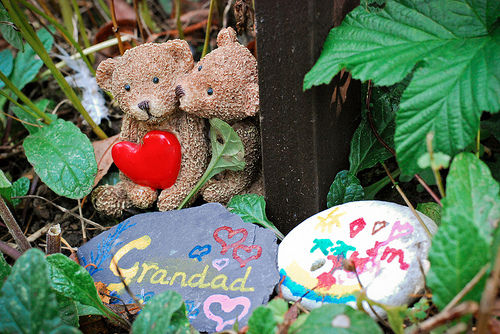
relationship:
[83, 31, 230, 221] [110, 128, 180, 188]
bear has heart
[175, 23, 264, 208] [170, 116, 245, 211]
stuffed animal in leaf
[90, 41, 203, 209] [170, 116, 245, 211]
stuffed animal in leaf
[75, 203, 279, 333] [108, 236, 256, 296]
rock with writing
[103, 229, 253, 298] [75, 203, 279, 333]
word written on rock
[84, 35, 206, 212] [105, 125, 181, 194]
bear holding heart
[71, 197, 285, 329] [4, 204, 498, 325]
rock on ground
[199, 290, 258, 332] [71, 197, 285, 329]
heart on rock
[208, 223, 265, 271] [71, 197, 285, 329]
hearts on rock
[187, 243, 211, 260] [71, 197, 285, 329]
heart on rock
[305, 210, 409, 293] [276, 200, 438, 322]
picture on painted rock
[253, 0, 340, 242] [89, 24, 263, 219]
post next to bears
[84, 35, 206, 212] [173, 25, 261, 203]
bear kissing bear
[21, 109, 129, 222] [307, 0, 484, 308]
leaves of plant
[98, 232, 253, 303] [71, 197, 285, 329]
word on rock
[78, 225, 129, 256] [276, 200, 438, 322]
blue writing on painted rock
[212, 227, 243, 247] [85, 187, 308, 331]
heart on stone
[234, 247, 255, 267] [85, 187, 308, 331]
heart on stone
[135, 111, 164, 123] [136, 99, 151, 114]
mouth on teddy bear nose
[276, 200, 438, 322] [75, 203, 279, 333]
painted rock next to rock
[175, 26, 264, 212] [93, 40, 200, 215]
bear kissing teddy bear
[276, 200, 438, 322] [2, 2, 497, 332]
painted rock on ground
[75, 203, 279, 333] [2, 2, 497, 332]
rock on ground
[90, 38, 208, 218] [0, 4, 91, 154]
bear kept near grass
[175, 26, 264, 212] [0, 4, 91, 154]
bear kept near grass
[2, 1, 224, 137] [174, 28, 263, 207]
grass near teddy bear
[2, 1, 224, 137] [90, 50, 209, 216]
grass near teddy bear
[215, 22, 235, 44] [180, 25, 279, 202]
ear of bear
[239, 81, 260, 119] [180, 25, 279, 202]
ear of bear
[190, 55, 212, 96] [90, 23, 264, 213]
eyes of bear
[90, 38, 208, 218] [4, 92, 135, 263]
bear kept in dirt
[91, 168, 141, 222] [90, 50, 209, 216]
leg of teddy bear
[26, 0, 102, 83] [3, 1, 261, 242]
grass leaf in ground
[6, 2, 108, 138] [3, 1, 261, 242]
grass leaf in ground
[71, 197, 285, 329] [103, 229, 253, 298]
rock with word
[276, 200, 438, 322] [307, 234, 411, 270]
painted rock with word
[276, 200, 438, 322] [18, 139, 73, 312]
painted rock in ground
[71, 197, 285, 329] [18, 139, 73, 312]
rock in ground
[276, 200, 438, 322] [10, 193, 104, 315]
painted rock in ground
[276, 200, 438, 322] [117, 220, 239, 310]
painted rock with words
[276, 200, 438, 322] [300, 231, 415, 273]
painted rock with word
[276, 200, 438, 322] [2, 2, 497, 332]
painted rock in ground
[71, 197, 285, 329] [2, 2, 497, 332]
rock in ground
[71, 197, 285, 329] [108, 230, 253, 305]
rock with words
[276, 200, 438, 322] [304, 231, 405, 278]
painted rock with words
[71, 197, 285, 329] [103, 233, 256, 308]
rock with word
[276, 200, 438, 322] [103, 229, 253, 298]
painted rock with word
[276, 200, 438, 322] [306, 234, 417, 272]
painted rock with word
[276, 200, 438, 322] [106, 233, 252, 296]
painted rock with word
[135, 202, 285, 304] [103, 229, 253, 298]
two rocks with word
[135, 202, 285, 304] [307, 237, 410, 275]
two rocks with word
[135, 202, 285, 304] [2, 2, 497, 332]
two rocks in ground